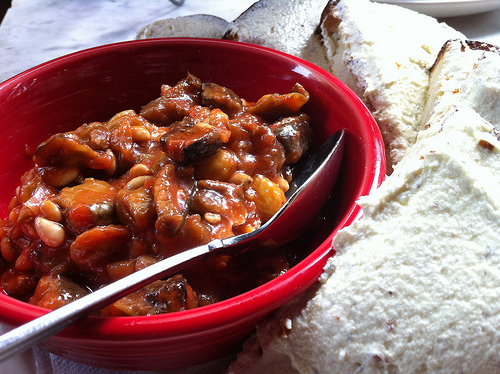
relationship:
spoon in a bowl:
[0, 125, 351, 359] [3, 29, 394, 364]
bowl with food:
[3, 29, 394, 364] [1, 68, 330, 315]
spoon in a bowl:
[0, 128, 347, 363] [3, 29, 394, 364]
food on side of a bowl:
[13, 78, 297, 312] [3, 29, 394, 364]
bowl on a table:
[3, 29, 394, 364] [0, 0, 500, 370]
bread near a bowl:
[347, 31, 495, 237] [3, 29, 394, 364]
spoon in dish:
[0, 125, 351, 359] [0, 28, 388, 346]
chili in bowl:
[8, 87, 338, 286] [0, 30, 450, 360]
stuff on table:
[0, 27, 377, 366] [2, 4, 107, 44]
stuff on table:
[181, 0, 499, 371] [2, 4, 107, 44]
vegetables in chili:
[6, 69, 316, 319] [47, 86, 264, 280]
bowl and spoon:
[3, 29, 394, 364] [0, 125, 351, 359]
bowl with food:
[0, 36, 387, 372] [4, 62, 355, 339]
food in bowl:
[13, 78, 297, 312] [3, 29, 394, 364]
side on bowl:
[33, 303, 283, 370] [3, 29, 394, 364]